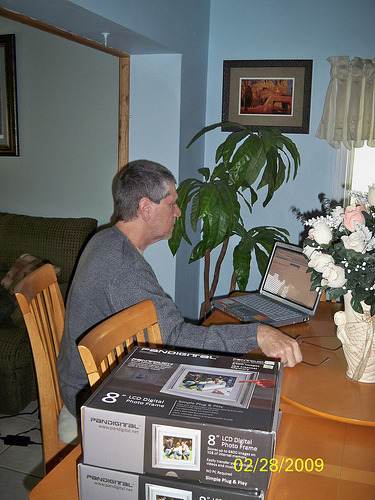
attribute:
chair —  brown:
[77, 296, 165, 390]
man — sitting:
[69, 162, 242, 367]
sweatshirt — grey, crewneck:
[63, 239, 260, 414]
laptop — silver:
[238, 231, 337, 337]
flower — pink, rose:
[333, 203, 371, 233]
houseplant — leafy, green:
[179, 126, 297, 246]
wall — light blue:
[75, 25, 354, 286]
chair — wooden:
[11, 260, 82, 388]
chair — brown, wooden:
[8, 274, 59, 387]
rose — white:
[314, 258, 346, 289]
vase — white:
[343, 320, 373, 354]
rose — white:
[311, 226, 339, 253]